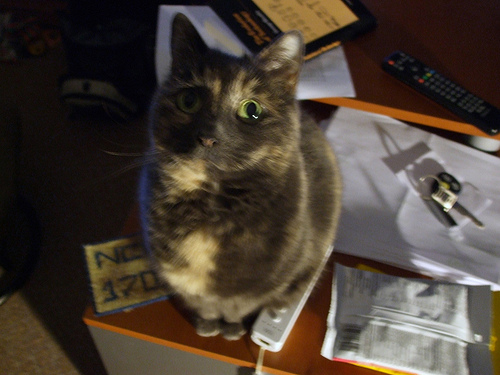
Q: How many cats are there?
A: 1.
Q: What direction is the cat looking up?
A: Up.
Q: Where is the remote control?
A: Behind the keys.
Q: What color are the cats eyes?
A: Green.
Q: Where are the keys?
A: Beside the cat.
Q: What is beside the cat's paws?
A: A wii controller.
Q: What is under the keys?
A: A stack of papers.